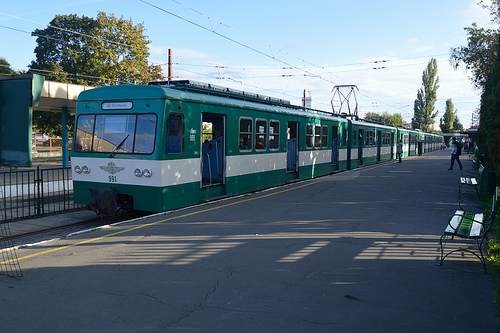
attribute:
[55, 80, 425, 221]
train — green, white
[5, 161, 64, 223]
gate — black, metal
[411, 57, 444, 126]
trees — cypress, leafy, green, large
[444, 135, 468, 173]
person — walking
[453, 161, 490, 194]
bench — empty, white, green, brown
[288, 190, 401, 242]
side walk — concrete, empty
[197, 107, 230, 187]
train door — open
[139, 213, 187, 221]
stripe — yellow